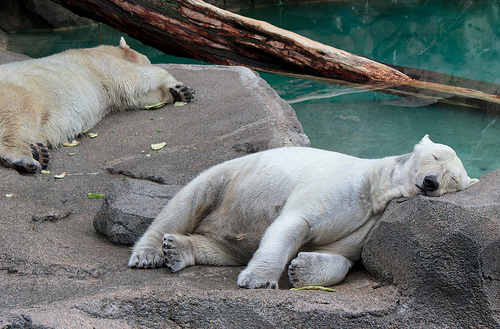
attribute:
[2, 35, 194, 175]
polar bears — big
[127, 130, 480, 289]
polar bears — big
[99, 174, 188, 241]
rock — grey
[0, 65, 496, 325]
ground — grey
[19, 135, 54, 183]
toes — black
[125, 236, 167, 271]
toes — black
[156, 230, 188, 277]
toes — black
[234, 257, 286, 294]
toes — black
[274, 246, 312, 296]
toes — white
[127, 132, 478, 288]
bear — white, laying down, resting, sleeping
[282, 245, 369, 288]
paw — white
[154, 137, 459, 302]
bear — white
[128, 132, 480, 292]
bears — white, sleeping, resting, laying down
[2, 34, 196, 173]
bears — laying down, resting, sleeping, tan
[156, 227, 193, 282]
paw — black, white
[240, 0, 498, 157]
water — blue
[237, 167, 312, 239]
fur — white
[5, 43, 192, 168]
bear — tan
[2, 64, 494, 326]
rocks — grey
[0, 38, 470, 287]
bears — sleeping, resting, laying down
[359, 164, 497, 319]
rock — grey 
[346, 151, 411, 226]
skin — white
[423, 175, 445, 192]
nose — black 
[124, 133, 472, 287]
polar bear — polar 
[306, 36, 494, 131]
log — brown, wooden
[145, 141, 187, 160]
rind — yellow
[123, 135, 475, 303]
bear — white, sleeping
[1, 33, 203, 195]
bear — tan, sleeping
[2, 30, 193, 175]
bear — laying down, resting, sleeping, tan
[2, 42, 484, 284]
polar bears — resting, sleeping, laying down